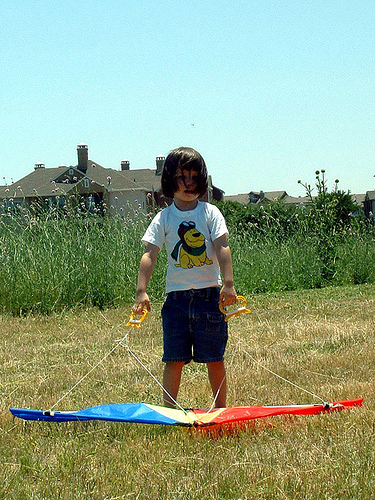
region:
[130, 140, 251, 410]
young girl in field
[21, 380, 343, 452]
kite on ground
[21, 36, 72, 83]
white clouds in blue sky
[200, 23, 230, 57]
white clouds in blue sky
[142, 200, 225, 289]
white cotton tee shirt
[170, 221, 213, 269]
decal on white shirt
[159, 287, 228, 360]
dark blue denim shorts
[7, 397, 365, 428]
blue red and yellow kite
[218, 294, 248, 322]
yellow handle of kite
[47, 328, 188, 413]
white rope on kite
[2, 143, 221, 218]
brown and white house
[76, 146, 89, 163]
stone chimney on roof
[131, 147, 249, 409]
child standing in grass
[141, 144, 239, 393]
young girl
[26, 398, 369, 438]
kite on ground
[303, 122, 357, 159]
white clouds in blue sky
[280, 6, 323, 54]
white clouds in blue sky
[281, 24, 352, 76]
white clouds in blue sky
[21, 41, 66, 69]
white clouds in blue sky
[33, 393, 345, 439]
colorful kite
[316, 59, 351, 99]
white clouds in blue sky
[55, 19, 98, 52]
white clouds in blue sky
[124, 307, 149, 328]
a yellow kite hook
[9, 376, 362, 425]
a long blue, red and yellow kite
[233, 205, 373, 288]
tall green grass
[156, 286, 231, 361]
a boy's blue jean shorts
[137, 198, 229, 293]
a boy's white shirt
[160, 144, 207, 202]
a boy's black hair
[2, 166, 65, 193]
a roof of a building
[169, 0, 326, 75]
part of a blue sky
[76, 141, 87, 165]
part of a chimney